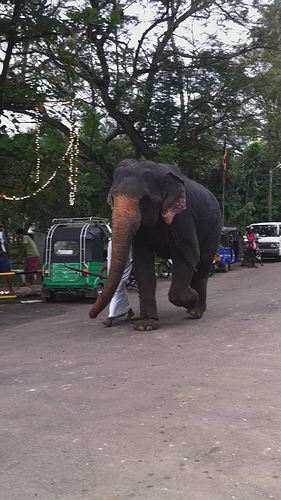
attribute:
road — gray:
[0, 262, 279, 499]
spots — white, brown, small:
[141, 407, 220, 490]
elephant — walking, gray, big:
[88, 160, 222, 333]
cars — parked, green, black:
[44, 219, 133, 296]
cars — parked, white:
[249, 223, 280, 259]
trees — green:
[0, 0, 279, 225]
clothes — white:
[106, 243, 129, 319]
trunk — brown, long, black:
[87, 195, 143, 320]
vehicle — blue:
[209, 230, 234, 272]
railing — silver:
[45, 217, 91, 277]